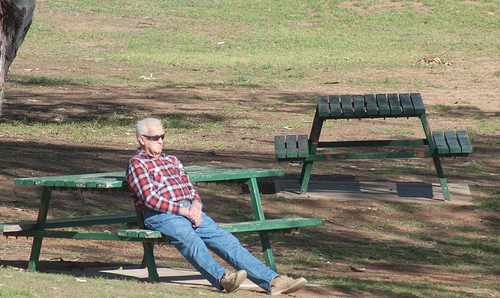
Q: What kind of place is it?
A: It is a park.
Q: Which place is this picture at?
A: It is at the park.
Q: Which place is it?
A: It is a park.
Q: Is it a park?
A: Yes, it is a park.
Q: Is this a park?
A: Yes, it is a park.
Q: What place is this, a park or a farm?
A: It is a park.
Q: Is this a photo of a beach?
A: No, the picture is showing a park.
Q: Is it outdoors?
A: Yes, it is outdoors.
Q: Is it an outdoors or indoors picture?
A: It is outdoors.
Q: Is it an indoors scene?
A: No, it is outdoors.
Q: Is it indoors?
A: No, it is outdoors.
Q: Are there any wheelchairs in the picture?
A: No, there are no wheelchairs.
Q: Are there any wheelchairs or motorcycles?
A: No, there are no wheelchairs or motorcycles.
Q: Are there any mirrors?
A: No, there are no mirrors.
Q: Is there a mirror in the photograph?
A: No, there are no mirrors.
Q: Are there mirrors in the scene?
A: No, there are no mirrors.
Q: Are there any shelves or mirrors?
A: No, there are no mirrors or shelves.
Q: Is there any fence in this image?
A: No, there are no fences.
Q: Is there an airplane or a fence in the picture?
A: No, there are no fences or airplanes.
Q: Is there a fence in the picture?
A: No, there are no fences.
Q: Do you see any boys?
A: No, there are no boys.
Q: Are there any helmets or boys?
A: No, there are no boys or helmets.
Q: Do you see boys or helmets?
A: No, there are no boys or helmets.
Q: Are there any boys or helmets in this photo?
A: No, there are no boys or helmets.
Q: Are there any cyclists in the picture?
A: No, there are no cyclists.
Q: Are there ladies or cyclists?
A: No, there are no cyclists or ladies.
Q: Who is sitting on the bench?
A: The man is sitting on the bench.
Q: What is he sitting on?
A: The man is sitting on the bench.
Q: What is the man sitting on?
A: The man is sitting on the bench.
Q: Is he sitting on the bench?
A: Yes, the man is sitting on the bench.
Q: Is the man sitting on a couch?
A: No, the man is sitting on the bench.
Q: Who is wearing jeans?
A: The man is wearing jeans.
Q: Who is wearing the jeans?
A: The man is wearing jeans.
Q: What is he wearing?
A: The man is wearing jeans.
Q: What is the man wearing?
A: The man is wearing jeans.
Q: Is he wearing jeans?
A: Yes, the man is wearing jeans.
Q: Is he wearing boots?
A: No, the man is wearing jeans.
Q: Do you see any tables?
A: Yes, there is a table.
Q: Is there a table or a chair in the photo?
A: Yes, there is a table.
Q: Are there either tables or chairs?
A: Yes, there is a table.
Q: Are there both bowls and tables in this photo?
A: No, there is a table but no bowls.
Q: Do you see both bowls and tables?
A: No, there is a table but no bowls.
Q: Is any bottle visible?
A: No, there are no bottles.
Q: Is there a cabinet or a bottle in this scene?
A: No, there are no bottles or cabinets.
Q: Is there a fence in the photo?
A: No, there are no fences.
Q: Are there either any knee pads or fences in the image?
A: No, there are no fences or knee pads.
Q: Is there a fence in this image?
A: No, there are no fences.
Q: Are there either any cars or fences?
A: No, there are no fences or cars.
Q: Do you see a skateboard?
A: No, there are no skateboards.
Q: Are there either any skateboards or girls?
A: No, there are no skateboards or girls.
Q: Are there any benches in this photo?
A: Yes, there is a bench.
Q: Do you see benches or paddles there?
A: Yes, there is a bench.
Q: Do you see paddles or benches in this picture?
A: Yes, there is a bench.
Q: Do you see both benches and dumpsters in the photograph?
A: No, there is a bench but no dumpsters.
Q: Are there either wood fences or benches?
A: Yes, there is a wood bench.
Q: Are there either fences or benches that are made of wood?
A: Yes, the bench is made of wood.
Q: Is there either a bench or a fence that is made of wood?
A: Yes, the bench is made of wood.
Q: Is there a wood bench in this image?
A: Yes, there is a wood bench.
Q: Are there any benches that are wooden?
A: Yes, there is a bench that is wooden.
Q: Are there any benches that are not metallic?
A: Yes, there is a wooden bench.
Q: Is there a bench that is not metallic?
A: Yes, there is a wooden bench.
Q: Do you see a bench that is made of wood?
A: Yes, there is a bench that is made of wood.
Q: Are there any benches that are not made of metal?
A: Yes, there is a bench that is made of wood.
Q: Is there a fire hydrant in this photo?
A: No, there are no fire hydrants.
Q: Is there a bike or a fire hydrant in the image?
A: No, there are no fire hydrants or bikes.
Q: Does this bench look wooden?
A: Yes, the bench is wooden.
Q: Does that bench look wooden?
A: Yes, the bench is wooden.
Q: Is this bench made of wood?
A: Yes, the bench is made of wood.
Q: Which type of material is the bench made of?
A: The bench is made of wood.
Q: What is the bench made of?
A: The bench is made of wood.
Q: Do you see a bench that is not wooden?
A: No, there is a bench but it is wooden.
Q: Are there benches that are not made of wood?
A: No, there is a bench but it is made of wood.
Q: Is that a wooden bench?
A: Yes, that is a wooden bench.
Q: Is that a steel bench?
A: No, that is a wooden bench.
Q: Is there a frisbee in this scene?
A: No, there are no frisbees.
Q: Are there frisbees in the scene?
A: No, there are no frisbees.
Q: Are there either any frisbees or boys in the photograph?
A: No, there are no frisbees or boys.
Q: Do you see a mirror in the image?
A: No, there are no mirrors.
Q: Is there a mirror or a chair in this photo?
A: No, there are no mirrors or chairs.